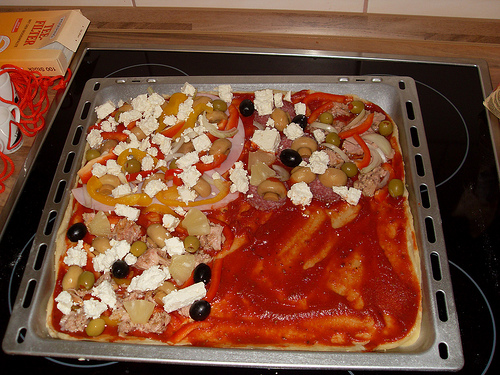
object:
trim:
[1, 5, 499, 90]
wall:
[1, 0, 499, 90]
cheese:
[226, 157, 251, 193]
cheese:
[158, 269, 213, 322]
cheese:
[221, 152, 256, 195]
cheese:
[100, 96, 130, 117]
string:
[0, 62, 71, 197]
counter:
[0, 7, 497, 214]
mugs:
[0, 103, 26, 154]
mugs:
[0, 68, 21, 106]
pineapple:
[122, 298, 159, 323]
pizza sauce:
[173, 190, 421, 348]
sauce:
[230, 214, 426, 344]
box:
[0, 6, 91, 80]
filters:
[40, 7, 82, 67]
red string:
[0, 63, 77, 205]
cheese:
[84, 242, 139, 283]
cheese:
[156, 270, 205, 323]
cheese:
[131, 172, 170, 204]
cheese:
[279, 168, 319, 213]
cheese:
[332, 180, 367, 211]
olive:
[188, 297, 216, 323]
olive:
[280, 146, 305, 167]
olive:
[66, 218, 86, 244]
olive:
[235, 95, 258, 116]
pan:
[398, 94, 459, 319]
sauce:
[47, 89, 419, 349]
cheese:
[230, 123, 297, 161]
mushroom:
[253, 179, 303, 210]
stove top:
[448, 122, 499, 303]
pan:
[3, 71, 465, 373]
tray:
[8, 73, 462, 367]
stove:
[0, 48, 493, 370]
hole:
[434, 290, 451, 322]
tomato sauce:
[233, 208, 420, 343]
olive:
[189, 299, 210, 321]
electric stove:
[434, 57, 499, 369]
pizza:
[51, 89, 444, 346]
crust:
[222, 208, 423, 345]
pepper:
[85, 177, 148, 209]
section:
[217, 199, 423, 356]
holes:
[424, 213, 437, 245]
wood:
[2, 6, 483, 74]